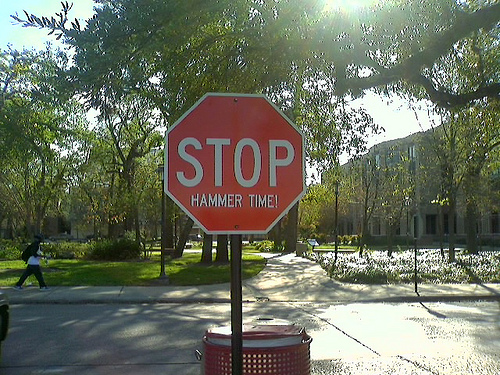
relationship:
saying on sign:
[172, 126, 302, 218] [150, 77, 330, 247]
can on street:
[173, 300, 334, 372] [15, 291, 482, 372]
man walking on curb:
[10, 224, 60, 296] [0, 277, 463, 322]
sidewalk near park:
[0, 264, 478, 313] [0, 202, 481, 285]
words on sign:
[187, 192, 279, 211] [157, 83, 311, 243]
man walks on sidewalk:
[12, 234, 51, 292] [4, 233, 329, 307]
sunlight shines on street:
[214, 299, 489, 373] [15, 291, 482, 372]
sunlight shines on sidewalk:
[214, 299, 489, 373] [4, 242, 498, 304]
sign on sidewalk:
[160, 91, 310, 236] [4, 248, 498, 308]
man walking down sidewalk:
[12, 234, 51, 292] [4, 248, 498, 308]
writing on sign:
[175, 129, 295, 211] [157, 83, 311, 243]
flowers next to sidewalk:
[317, 244, 497, 285] [4, 248, 498, 308]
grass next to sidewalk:
[6, 248, 260, 288] [4, 244, 492, 310]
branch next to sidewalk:
[329, 1, 497, 100] [4, 248, 498, 308]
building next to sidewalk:
[312, 97, 498, 244] [4, 248, 498, 308]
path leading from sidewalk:
[156, 242, 336, 312] [5, 272, 498, 303]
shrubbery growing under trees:
[78, 233, 140, 268] [6, 1, 176, 258]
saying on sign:
[187, 188, 279, 214] [160, 91, 310, 236]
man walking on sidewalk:
[12, 234, 51, 292] [4, 244, 323, 306]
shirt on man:
[17, 247, 50, 272] [12, 234, 51, 292]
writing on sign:
[171, 133, 298, 192] [157, 83, 311, 243]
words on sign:
[165, 72, 337, 254] [155, 69, 344, 369]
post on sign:
[170, 185, 300, 354] [147, 53, 341, 369]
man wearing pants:
[12, 234, 51, 292] [15, 260, 50, 326]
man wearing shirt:
[12, 234, 51, 292] [18, 211, 54, 276]